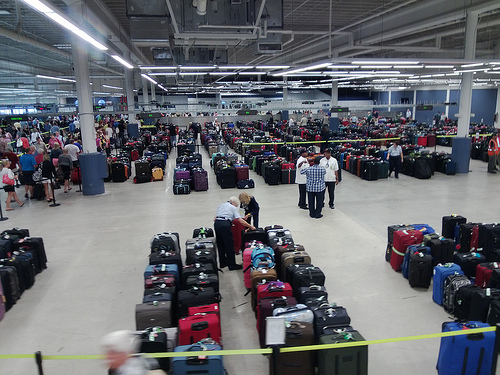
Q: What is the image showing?
A: It is showing an airport.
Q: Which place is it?
A: It is an airport.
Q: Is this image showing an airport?
A: Yes, it is showing an airport.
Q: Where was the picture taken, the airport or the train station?
A: It was taken at the airport.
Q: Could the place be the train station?
A: No, it is the airport.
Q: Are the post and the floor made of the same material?
A: Yes, both the post and the floor are made of concrete.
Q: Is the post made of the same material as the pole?
A: Yes, both the post and the pole are made of cement.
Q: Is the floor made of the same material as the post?
A: Yes, both the floor and the post are made of concrete.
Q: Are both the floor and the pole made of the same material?
A: Yes, both the floor and the pole are made of concrete.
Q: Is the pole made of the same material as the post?
A: Yes, both the pole and the post are made of cement.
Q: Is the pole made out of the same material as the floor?
A: Yes, both the pole and the floor are made of concrete.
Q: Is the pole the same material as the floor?
A: Yes, both the pole and the floor are made of concrete.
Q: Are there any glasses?
A: No, there are no glasses.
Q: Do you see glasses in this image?
A: No, there are no glasses.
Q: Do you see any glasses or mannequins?
A: No, there are no glasses or mannequins.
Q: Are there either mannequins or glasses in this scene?
A: No, there are no glasses or mannequins.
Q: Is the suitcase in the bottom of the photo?
A: Yes, the suitcase is in the bottom of the image.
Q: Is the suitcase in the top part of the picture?
A: No, the suitcase is in the bottom of the image.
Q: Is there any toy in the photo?
A: No, there are no toys.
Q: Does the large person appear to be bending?
A: Yes, the person is bending.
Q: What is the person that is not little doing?
A: The person is bending.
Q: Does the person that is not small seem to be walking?
A: No, the person is bending.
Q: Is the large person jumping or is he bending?
A: The person is bending.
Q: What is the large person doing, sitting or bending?
A: The person is bending.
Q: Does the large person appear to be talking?
A: Yes, the person is talking.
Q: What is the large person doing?
A: The person is talking.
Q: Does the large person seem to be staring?
A: No, the person is talking.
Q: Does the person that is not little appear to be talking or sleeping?
A: The person is talking.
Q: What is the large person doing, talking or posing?
A: The person is talking.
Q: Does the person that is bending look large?
A: Yes, the person is large.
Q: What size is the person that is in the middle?
A: The person is large.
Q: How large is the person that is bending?
A: The person is large.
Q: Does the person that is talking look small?
A: No, the person is large.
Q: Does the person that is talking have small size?
A: No, the person is large.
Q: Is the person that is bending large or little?
A: The person is large.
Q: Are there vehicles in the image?
A: No, there are no vehicles.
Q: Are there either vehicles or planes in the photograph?
A: No, there are no vehicles or planes.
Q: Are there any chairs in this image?
A: No, there are no chairs.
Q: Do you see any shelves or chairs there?
A: No, there are no chairs or shelves.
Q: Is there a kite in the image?
A: No, there are no kites.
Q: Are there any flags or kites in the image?
A: No, there are no kites or flags.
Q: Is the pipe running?
A: Yes, the pipe is running.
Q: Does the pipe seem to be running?
A: Yes, the pipe is running.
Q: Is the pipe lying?
A: No, the pipe is running.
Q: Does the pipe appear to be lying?
A: No, the pipe is running.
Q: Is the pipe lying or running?
A: The pipe is running.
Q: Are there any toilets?
A: No, there are no toilets.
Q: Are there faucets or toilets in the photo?
A: No, there are no toilets or faucets.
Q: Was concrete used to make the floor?
A: Yes, the floor is made of concrete.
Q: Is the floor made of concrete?
A: Yes, the floor is made of concrete.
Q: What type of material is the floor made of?
A: The floor is made of concrete.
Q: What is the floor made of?
A: The floor is made of concrete.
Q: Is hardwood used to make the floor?
A: No, the floor is made of concrete.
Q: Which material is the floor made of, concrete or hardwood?
A: The floor is made of concrete.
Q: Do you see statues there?
A: No, there are no statues.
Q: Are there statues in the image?
A: No, there are no statues.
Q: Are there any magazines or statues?
A: No, there are no statues or magazines.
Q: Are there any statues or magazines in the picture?
A: No, there are no statues or magazines.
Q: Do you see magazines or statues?
A: No, there are no statues or magazines.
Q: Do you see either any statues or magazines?
A: No, there are no statues or magazines.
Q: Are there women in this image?
A: Yes, there is a woman.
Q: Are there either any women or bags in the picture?
A: Yes, there is a woman.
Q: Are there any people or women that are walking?
A: Yes, the woman is walking.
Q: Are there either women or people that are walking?
A: Yes, the woman is walking.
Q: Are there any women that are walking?
A: Yes, there is a woman that is walking.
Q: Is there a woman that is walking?
A: Yes, there is a woman that is walking.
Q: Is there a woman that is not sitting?
A: Yes, there is a woman that is walking.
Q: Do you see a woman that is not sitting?
A: Yes, there is a woman that is walking .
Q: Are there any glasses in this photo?
A: No, there are no glasses.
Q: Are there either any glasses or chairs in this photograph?
A: No, there are no glasses or chairs.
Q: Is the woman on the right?
A: Yes, the woman is on the right of the image.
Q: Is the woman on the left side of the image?
A: No, the woman is on the right of the image.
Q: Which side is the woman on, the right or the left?
A: The woman is on the right of the image.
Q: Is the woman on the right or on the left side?
A: The woman is on the right of the image.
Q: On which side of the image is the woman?
A: The woman is on the right of the image.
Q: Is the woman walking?
A: Yes, the woman is walking.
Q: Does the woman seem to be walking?
A: Yes, the woman is walking.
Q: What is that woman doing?
A: The woman is walking.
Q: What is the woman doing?
A: The woman is walking.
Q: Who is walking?
A: The woman is walking.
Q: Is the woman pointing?
A: No, the woman is walking.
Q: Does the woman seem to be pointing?
A: No, the woman is walking.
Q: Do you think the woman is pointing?
A: No, the woman is walking.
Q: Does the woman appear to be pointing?
A: No, the woman is walking.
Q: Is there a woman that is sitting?
A: No, there is a woman but she is walking.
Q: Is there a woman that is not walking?
A: No, there is a woman but she is walking.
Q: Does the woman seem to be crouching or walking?
A: The woman is walking.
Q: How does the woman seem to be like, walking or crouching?
A: The woman is walking.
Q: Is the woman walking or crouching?
A: The woman is walking.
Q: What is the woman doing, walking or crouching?
A: The woman is walking.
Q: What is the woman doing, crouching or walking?
A: The woman is walking.